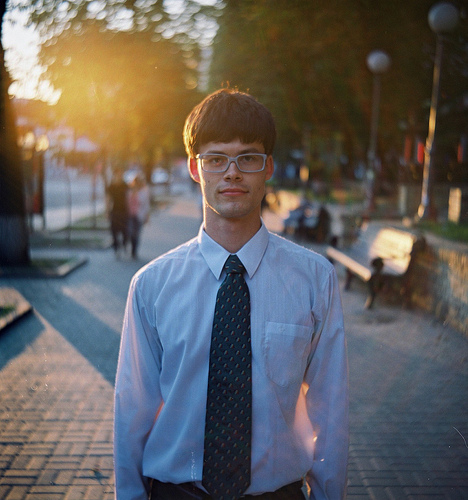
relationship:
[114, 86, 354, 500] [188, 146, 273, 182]
man wearing glasses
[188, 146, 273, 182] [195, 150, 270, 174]
glasses have frames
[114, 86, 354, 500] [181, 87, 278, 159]
man has hair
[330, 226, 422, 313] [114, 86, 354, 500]
bench behind man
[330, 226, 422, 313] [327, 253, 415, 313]
bench has legs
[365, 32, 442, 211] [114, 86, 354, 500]
lamppost behind man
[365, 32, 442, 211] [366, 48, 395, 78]
lamppost has globe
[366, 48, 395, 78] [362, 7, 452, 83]
globe on top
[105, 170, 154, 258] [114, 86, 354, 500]
couple behind man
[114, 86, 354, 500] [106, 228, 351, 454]
man wearing shirt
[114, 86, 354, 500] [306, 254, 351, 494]
man has arms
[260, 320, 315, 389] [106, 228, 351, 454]
pocket on shirt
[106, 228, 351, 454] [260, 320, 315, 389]
shirt has pocket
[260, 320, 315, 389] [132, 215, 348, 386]
pocket on front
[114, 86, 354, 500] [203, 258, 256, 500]
man wearing tie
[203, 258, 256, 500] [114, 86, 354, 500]
tie on man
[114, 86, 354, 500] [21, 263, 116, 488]
man on sidewalk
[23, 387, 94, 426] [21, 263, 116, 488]
brick on sidewalk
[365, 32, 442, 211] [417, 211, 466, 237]
lamppost on grass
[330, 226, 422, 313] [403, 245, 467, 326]
bench beside wall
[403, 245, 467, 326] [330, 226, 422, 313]
wall near bench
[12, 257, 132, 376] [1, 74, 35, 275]
shadow of lamppost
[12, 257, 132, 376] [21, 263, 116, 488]
shadow on sidewalk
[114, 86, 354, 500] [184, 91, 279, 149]
man has hair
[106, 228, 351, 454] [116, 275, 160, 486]
shirt has sleeves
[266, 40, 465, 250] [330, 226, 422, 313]
park has bench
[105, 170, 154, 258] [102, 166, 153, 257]
couple walking together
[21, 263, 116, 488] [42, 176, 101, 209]
sidewalk beside road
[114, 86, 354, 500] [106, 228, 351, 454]
man in shirt